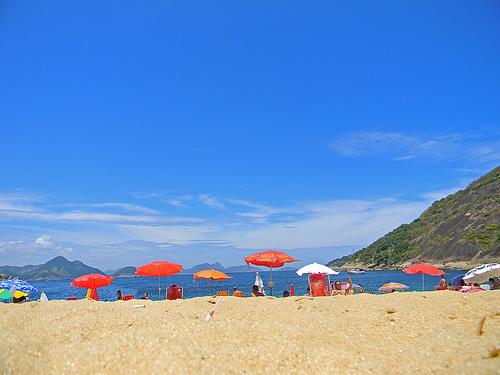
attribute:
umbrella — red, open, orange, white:
[131, 263, 177, 301]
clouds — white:
[3, 194, 361, 247]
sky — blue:
[3, 7, 500, 261]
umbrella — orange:
[196, 270, 231, 296]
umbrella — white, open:
[294, 264, 337, 277]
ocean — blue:
[5, 271, 488, 293]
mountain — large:
[4, 254, 104, 283]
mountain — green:
[320, 161, 499, 273]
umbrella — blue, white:
[455, 257, 499, 283]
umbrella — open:
[239, 249, 295, 300]